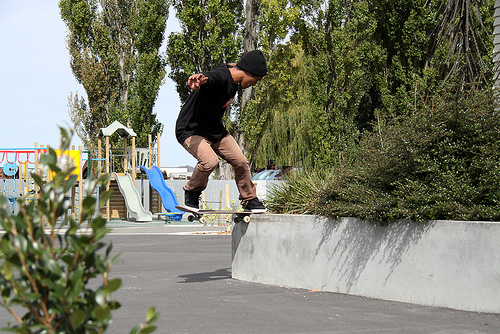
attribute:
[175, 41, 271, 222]
skateboarder — male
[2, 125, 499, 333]
park — playground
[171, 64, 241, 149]
shirt — black, t shirt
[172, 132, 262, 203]
pants — brown, tan, khaki, beige, jeans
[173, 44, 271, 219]
man — skateboarding, young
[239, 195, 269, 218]
shoe — sneaker, black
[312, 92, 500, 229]
bush — leafy, green, overgrown, large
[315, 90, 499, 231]
leaves — green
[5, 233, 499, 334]
sidewalk — grey, gray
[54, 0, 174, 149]
leaves — green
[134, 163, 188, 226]
slide — blue, plastic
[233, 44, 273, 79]
cap — black, skull cap, knit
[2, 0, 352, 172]
sky — light blue, blue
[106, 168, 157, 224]
slide — grey, white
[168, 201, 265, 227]
skateboard — brown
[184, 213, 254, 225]
wheels — white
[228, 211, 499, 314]
wall — yellow, concrete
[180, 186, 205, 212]
shoe — black, sneaker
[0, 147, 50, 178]
monkey bars — red